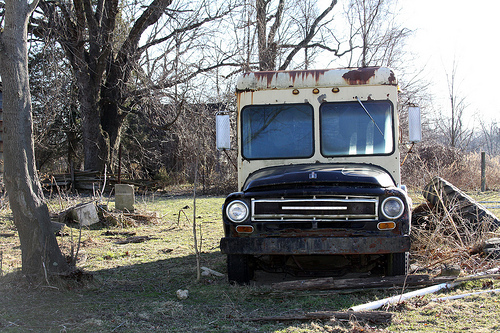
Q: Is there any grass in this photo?
A: Yes, there is grass.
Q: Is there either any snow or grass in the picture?
A: Yes, there is grass.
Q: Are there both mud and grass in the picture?
A: No, there is grass but no mud.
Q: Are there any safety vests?
A: No, there are no safety vests.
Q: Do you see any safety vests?
A: No, there are no safety vests.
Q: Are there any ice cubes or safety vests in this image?
A: No, there are no safety vests or ice cubes.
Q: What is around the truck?
A: The grass is around the truck.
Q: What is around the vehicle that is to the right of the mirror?
A: The grass is around the truck.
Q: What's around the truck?
A: The grass is around the truck.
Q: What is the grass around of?
A: The grass is around the truck.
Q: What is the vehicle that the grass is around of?
A: The vehicle is a truck.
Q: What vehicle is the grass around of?
A: The grass is around the truck.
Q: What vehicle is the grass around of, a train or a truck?
A: The grass is around a truck.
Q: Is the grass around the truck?
A: Yes, the grass is around the truck.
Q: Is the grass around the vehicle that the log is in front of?
A: Yes, the grass is around the truck.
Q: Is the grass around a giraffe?
A: No, the grass is around the truck.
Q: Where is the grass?
A: The grass is on the ground.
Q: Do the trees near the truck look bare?
A: Yes, the trees are bare.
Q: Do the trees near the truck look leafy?
A: No, the trees are bare.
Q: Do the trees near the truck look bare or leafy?
A: The trees are bare.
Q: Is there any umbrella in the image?
A: No, there are no umbrellas.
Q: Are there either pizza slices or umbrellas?
A: No, there are no umbrellas or pizza slices.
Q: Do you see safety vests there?
A: No, there are no safety vests.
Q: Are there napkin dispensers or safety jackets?
A: No, there are no safety jackets or napkin dispensers.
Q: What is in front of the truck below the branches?
A: The log is in front of the truck.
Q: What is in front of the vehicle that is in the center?
A: The log is in front of the truck.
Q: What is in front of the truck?
A: The log is in front of the truck.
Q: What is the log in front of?
A: The log is in front of the truck.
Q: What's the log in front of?
A: The log is in front of the truck.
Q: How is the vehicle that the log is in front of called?
A: The vehicle is a truck.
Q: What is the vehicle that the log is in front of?
A: The vehicle is a truck.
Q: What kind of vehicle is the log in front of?
A: The log is in front of the truck.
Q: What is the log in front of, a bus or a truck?
A: The log is in front of a truck.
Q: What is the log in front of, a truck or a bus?
A: The log is in front of a truck.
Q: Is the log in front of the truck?
A: Yes, the log is in front of the truck.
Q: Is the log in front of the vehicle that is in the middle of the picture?
A: Yes, the log is in front of the truck.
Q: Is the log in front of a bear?
A: No, the log is in front of the truck.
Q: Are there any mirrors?
A: Yes, there is a mirror.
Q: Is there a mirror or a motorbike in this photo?
A: Yes, there is a mirror.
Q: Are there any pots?
A: No, there are no pots.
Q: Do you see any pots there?
A: No, there are no pots.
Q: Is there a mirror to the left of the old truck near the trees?
A: Yes, there is a mirror to the left of the truck.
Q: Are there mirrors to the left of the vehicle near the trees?
A: Yes, there is a mirror to the left of the truck.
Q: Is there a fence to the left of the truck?
A: No, there is a mirror to the left of the truck.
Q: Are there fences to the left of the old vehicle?
A: No, there is a mirror to the left of the truck.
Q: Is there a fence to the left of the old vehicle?
A: No, there is a mirror to the left of the truck.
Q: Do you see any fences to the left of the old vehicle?
A: No, there is a mirror to the left of the truck.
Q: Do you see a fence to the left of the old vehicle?
A: No, there is a mirror to the left of the truck.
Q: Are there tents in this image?
A: No, there are no tents.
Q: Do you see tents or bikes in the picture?
A: No, there are no tents or bikes.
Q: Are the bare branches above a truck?
A: Yes, the branches are above a truck.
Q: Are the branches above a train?
A: No, the branches are above a truck.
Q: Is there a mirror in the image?
A: Yes, there is a mirror.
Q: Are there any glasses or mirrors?
A: Yes, there is a mirror.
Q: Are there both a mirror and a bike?
A: No, there is a mirror but no bikes.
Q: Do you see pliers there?
A: No, there are no pliers.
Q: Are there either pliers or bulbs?
A: No, there are no pliers or bulbs.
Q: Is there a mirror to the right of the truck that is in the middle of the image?
A: Yes, there is a mirror to the right of the truck.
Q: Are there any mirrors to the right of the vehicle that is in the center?
A: Yes, there is a mirror to the right of the truck.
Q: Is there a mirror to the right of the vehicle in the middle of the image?
A: Yes, there is a mirror to the right of the truck.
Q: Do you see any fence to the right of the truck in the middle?
A: No, there is a mirror to the right of the truck.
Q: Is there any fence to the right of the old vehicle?
A: No, there is a mirror to the right of the truck.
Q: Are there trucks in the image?
A: Yes, there is a truck.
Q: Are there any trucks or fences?
A: Yes, there is a truck.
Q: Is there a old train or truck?
A: Yes, there is an old truck.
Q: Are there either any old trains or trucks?
A: Yes, there is an old truck.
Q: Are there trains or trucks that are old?
A: Yes, the truck is old.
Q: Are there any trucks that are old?
A: Yes, there is an old truck.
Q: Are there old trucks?
A: Yes, there is an old truck.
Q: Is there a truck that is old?
A: Yes, there is a truck that is old.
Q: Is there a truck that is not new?
A: Yes, there is a old truck.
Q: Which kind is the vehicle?
A: The vehicle is a truck.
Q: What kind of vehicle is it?
A: The vehicle is a truck.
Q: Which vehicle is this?
A: This is a truck.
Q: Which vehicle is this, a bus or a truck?
A: This is a truck.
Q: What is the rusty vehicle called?
A: The vehicle is a truck.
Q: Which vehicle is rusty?
A: The vehicle is a truck.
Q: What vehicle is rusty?
A: The vehicle is a truck.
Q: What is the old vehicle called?
A: The vehicle is a truck.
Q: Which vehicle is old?
A: The vehicle is a truck.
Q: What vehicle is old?
A: The vehicle is a truck.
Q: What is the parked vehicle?
A: The vehicle is a truck.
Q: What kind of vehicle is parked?
A: The vehicle is a truck.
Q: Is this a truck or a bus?
A: This is a truck.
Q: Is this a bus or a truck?
A: This is a truck.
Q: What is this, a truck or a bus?
A: This is a truck.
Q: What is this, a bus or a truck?
A: This is a truck.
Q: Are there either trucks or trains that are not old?
A: No, there is a truck but it is old.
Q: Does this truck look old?
A: Yes, the truck is old.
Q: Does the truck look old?
A: Yes, the truck is old.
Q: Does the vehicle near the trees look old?
A: Yes, the truck is old.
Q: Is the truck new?
A: No, the truck is old.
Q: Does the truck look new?
A: No, the truck is old.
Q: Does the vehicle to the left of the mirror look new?
A: No, the truck is old.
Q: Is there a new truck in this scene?
A: No, there is a truck but it is old.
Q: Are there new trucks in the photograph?
A: No, there is a truck but it is old.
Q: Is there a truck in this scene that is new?
A: No, there is a truck but it is old.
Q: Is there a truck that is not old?
A: No, there is a truck but it is old.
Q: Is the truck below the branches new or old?
A: The truck is old.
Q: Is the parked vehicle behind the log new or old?
A: The truck is old.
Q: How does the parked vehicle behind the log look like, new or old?
A: The truck is old.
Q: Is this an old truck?
A: Yes, this is an old truck.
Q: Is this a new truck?
A: No, this is an old truck.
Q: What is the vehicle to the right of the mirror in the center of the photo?
A: The vehicle is a truck.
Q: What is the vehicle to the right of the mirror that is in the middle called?
A: The vehicle is a truck.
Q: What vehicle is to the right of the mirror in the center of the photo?
A: The vehicle is a truck.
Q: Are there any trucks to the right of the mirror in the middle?
A: Yes, there is a truck to the right of the mirror.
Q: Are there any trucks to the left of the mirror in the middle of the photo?
A: No, the truck is to the right of the mirror.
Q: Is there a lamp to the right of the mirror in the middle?
A: No, there is a truck to the right of the mirror.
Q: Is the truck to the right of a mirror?
A: Yes, the truck is to the right of a mirror.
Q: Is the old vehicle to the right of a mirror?
A: Yes, the truck is to the right of a mirror.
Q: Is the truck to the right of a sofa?
A: No, the truck is to the right of a mirror.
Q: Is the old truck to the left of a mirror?
A: No, the truck is to the right of a mirror.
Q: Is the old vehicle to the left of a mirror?
A: No, the truck is to the right of a mirror.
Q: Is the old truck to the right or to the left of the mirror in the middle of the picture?
A: The truck is to the right of the mirror.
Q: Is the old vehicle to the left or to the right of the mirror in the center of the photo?
A: The truck is to the right of the mirror.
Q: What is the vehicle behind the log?
A: The vehicle is a truck.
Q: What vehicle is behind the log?
A: The vehicle is a truck.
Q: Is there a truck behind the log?
A: Yes, there is a truck behind the log.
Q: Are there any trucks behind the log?
A: Yes, there is a truck behind the log.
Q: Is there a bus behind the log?
A: No, there is a truck behind the log.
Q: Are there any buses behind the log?
A: No, there is a truck behind the log.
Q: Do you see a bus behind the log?
A: No, there is a truck behind the log.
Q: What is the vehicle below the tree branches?
A: The vehicle is a truck.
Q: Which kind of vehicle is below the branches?
A: The vehicle is a truck.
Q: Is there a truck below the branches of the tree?
A: Yes, there is a truck below the branches.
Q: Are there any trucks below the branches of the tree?
A: Yes, there is a truck below the branches.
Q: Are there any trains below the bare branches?
A: No, there is a truck below the branches.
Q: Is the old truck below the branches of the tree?
A: Yes, the truck is below the branches.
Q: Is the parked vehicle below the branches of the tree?
A: Yes, the truck is below the branches.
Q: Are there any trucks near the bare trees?
A: Yes, there is a truck near the trees.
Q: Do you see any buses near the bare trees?
A: No, there is a truck near the trees.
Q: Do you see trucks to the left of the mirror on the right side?
A: Yes, there is a truck to the left of the mirror.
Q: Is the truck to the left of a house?
A: No, the truck is to the left of a mirror.